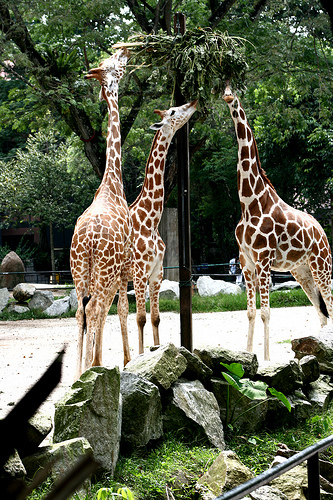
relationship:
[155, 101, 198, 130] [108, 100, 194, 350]
head of giraffe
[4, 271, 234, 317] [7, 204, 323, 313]
rocks in background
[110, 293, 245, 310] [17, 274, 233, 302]
grass in front rocks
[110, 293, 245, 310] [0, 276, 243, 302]
grass in front rocks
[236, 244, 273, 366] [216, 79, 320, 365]
feet of giraffe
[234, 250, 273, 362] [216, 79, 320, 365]
feet of giraffe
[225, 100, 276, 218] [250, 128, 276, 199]
neck has mane